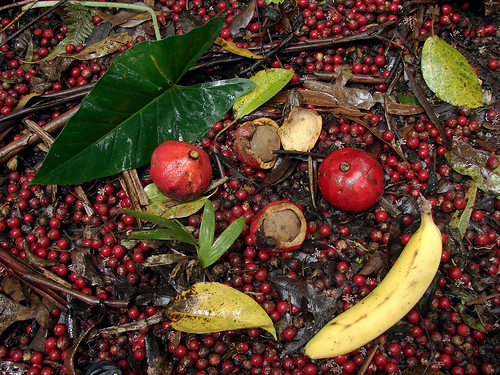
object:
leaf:
[23, 15, 251, 187]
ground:
[0, 0, 499, 375]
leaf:
[165, 281, 277, 346]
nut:
[249, 199, 307, 252]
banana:
[299, 205, 443, 361]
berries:
[6, 206, 77, 276]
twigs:
[312, 71, 386, 84]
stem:
[147, 302, 167, 309]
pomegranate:
[149, 140, 213, 202]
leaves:
[420, 35, 484, 109]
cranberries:
[313, 5, 355, 30]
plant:
[118, 199, 247, 284]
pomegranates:
[317, 148, 384, 213]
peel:
[331, 329, 361, 348]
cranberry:
[65, 44, 86, 54]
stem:
[415, 192, 433, 222]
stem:
[188, 149, 200, 160]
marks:
[344, 249, 420, 329]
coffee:
[438, 305, 494, 362]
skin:
[165, 163, 200, 193]